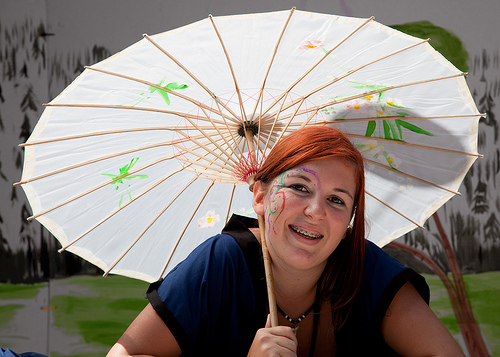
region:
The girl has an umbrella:
[18, 9, 480, 356]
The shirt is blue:
[145, 232, 427, 355]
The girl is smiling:
[252, 126, 363, 266]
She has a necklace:
[271, 290, 321, 333]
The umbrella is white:
[20, 11, 473, 281]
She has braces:
[286, 220, 324, 245]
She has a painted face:
[262, 167, 322, 231]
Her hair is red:
[255, 124, 366, 310]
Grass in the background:
[60, 271, 134, 333]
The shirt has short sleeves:
[150, 229, 430, 354]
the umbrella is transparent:
[41, 45, 463, 260]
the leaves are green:
[381, 77, 417, 148]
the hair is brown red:
[275, 118, 361, 168]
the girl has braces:
[288, 220, 341, 258]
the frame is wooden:
[36, 56, 478, 241]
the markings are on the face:
[268, 179, 302, 235]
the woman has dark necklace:
[284, 300, 335, 344]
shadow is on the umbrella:
[346, 93, 460, 198]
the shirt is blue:
[178, 255, 265, 341]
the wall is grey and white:
[20, 25, 95, 55]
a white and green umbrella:
[10, 6, 491, 289]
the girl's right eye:
[282, 180, 312, 197]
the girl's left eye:
[321, 185, 349, 210]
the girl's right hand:
[241, 305, 302, 355]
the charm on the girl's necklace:
[286, 322, 303, 337]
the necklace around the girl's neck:
[268, 290, 324, 333]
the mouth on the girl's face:
[284, 218, 327, 247]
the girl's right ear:
[246, 173, 272, 216]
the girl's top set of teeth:
[289, 222, 328, 239]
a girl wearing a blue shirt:
[102, 121, 481, 355]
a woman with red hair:
[253, 125, 365, 333]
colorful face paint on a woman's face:
[266, 161, 321, 241]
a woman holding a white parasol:
[16, 15, 481, 354]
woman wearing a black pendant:
[272, 294, 319, 335]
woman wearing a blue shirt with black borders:
[149, 214, 431, 354]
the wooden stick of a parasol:
[251, 180, 281, 355]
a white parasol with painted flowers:
[16, 7, 478, 284]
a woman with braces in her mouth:
[288, 220, 325, 248]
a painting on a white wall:
[2, 5, 496, 279]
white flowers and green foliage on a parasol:
[360, 80, 435, 140]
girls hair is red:
[329, 130, 362, 285]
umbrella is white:
[46, 43, 475, 142]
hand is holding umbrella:
[55, 53, 276, 354]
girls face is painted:
[271, 163, 285, 261]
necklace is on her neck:
[281, 313, 325, 350]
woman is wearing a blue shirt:
[168, 228, 253, 346]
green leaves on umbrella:
[375, 96, 407, 176]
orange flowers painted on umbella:
[349, 86, 376, 128]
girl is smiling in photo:
[281, 219, 318, 244]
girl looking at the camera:
[241, 125, 370, 302]